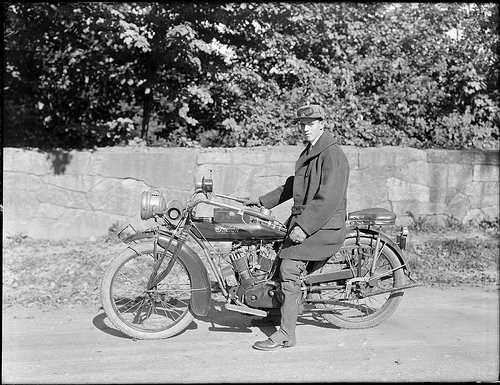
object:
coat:
[256, 129, 348, 260]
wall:
[4, 145, 499, 245]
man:
[244, 106, 349, 351]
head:
[295, 104, 326, 143]